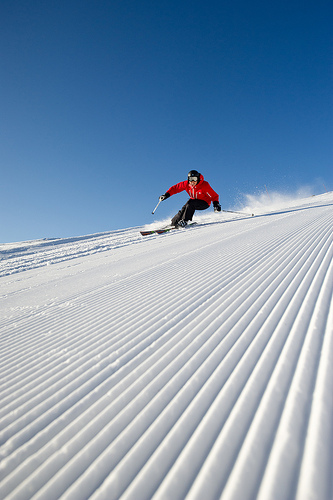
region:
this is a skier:
[161, 182, 223, 240]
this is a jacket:
[153, 181, 217, 210]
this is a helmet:
[163, 173, 210, 201]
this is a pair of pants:
[131, 199, 249, 277]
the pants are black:
[128, 203, 202, 269]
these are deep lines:
[150, 370, 286, 489]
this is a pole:
[143, 197, 237, 249]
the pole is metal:
[131, 172, 176, 244]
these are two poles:
[121, 182, 160, 235]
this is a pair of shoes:
[158, 205, 209, 256]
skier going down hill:
[130, 164, 242, 250]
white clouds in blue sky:
[59, 79, 100, 108]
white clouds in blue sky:
[177, 76, 196, 102]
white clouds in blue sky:
[223, 34, 287, 81]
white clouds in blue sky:
[27, 28, 56, 66]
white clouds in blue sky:
[33, 92, 55, 116]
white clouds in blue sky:
[39, 129, 78, 163]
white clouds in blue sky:
[16, 164, 40, 181]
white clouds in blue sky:
[87, 68, 128, 91]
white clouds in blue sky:
[84, 92, 130, 141]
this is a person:
[125, 141, 235, 236]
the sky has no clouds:
[61, 157, 120, 210]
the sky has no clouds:
[114, 69, 189, 133]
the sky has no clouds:
[272, 155, 294, 179]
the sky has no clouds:
[47, 54, 134, 158]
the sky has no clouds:
[194, 78, 281, 186]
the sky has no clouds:
[84, 48, 178, 187]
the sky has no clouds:
[119, 55, 282, 114]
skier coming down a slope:
[17, 129, 325, 499]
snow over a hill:
[0, 203, 330, 498]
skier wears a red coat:
[151, 159, 216, 222]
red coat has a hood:
[161, 174, 215, 204]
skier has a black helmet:
[172, 162, 209, 197]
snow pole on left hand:
[205, 199, 260, 218]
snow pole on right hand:
[146, 190, 169, 218]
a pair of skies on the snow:
[132, 220, 197, 231]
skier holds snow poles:
[136, 162, 257, 221]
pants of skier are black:
[149, 159, 229, 234]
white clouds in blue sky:
[21, 43, 74, 88]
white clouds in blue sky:
[253, 106, 305, 133]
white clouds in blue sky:
[80, 168, 108, 195]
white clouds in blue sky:
[205, 106, 243, 142]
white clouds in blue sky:
[111, 54, 160, 98]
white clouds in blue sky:
[214, 28, 274, 62]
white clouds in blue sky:
[105, 53, 131, 104]